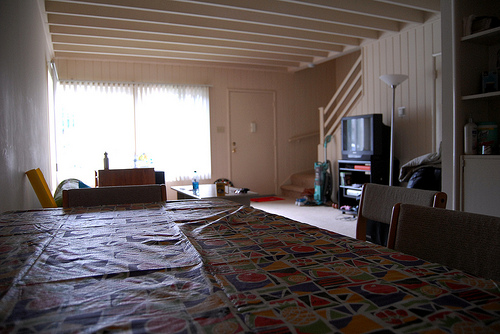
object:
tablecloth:
[0, 198, 499, 334]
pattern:
[363, 283, 398, 293]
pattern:
[340, 314, 385, 333]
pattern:
[245, 314, 286, 330]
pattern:
[275, 301, 317, 326]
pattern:
[375, 309, 408, 325]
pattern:
[313, 276, 353, 290]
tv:
[341, 114, 392, 161]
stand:
[337, 158, 400, 218]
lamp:
[379, 74, 408, 186]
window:
[55, 80, 212, 185]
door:
[229, 89, 278, 195]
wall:
[276, 59, 337, 196]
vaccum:
[313, 135, 331, 205]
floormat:
[250, 196, 285, 202]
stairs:
[280, 169, 316, 199]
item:
[481, 70, 499, 93]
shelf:
[461, 91, 498, 99]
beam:
[43, 1, 439, 67]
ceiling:
[37, 0, 441, 74]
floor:
[250, 195, 358, 239]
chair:
[388, 203, 500, 281]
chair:
[62, 184, 167, 208]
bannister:
[318, 55, 362, 144]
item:
[214, 178, 230, 196]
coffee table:
[170, 184, 259, 207]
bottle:
[191, 171, 199, 190]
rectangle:
[287, 281, 324, 296]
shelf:
[459, 26, 499, 41]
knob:
[232, 148, 236, 152]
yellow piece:
[25, 167, 58, 208]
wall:
[0, 1, 57, 214]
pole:
[389, 85, 397, 186]